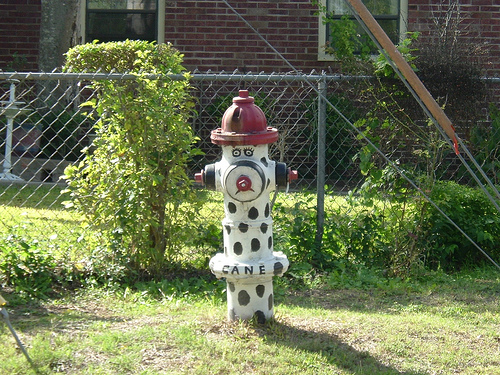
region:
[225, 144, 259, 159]
the hydrant has eyes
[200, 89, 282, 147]
the top of the hydrant is red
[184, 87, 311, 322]
the hydrant is polkadotted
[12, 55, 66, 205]
the fence is metal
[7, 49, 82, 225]
the fence is short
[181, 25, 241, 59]
the wall is brick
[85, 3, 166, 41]
the window is closed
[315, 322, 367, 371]
the shadow is on the ground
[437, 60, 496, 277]
the wires are thick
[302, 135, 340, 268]
the pole is thin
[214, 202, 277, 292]
spots on the firehydrant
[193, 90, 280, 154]
top of the firehydrant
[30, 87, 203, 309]
bush behind the fire hydrant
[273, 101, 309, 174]
mesh of the wire fence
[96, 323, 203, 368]
grass on the ground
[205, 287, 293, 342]
base of the fire hydrant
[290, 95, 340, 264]
pole of the fence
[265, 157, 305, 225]
nozzle of the fire hydrant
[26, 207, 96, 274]
light reflecting off the leaves of the bushes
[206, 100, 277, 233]
face of the fire hydrant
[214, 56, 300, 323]
a water pipe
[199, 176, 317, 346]
a water pipe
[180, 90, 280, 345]
a water pipe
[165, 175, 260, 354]
a water pipe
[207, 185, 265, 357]
a water pipe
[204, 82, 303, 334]
fire hydrant on grass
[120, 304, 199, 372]
clumps of dried brown grass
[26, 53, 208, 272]
short metal fence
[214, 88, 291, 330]
black and white fire hydrant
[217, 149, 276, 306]
white fire hydrant with black spots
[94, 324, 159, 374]
clumps of green grass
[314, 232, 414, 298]
green plants growing on fence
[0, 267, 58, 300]
green plants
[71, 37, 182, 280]
small green bush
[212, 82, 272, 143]
red top of fire hydrant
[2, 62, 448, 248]
A metal chain link fence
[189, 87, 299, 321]
A fire hydrant painted like a dalmatian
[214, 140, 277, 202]
A frowning face on a fire hydrant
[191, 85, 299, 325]
A red, white, and black fire hydrant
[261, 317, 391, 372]
The shadow of a fire hydrant in the grass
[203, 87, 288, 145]
The red top of a fire hydrant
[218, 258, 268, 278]
The word CANE written in black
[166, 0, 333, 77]
The wall of a brick house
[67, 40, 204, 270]
A tall thin hedge by a fence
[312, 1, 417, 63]
The window of a building